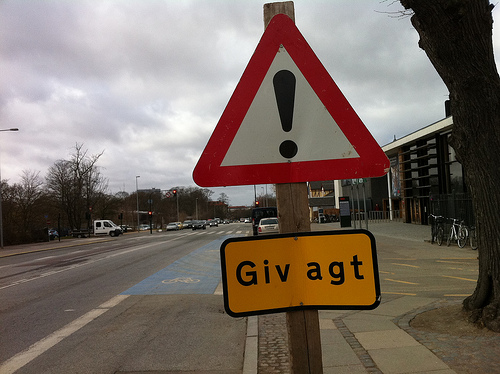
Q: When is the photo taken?
A: Daytime.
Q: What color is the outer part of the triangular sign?
A: Red.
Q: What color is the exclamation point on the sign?
A: Black.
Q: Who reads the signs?
A: Drivers.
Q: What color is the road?
A: Gray.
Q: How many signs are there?
A: Two.